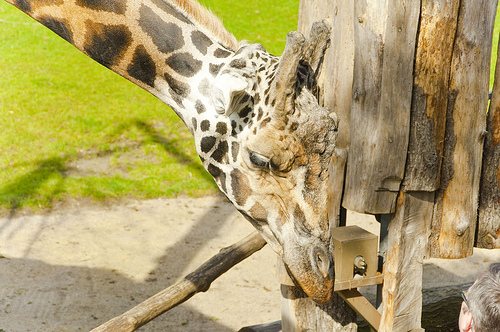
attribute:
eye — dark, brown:
[253, 158, 290, 184]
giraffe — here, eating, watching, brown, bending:
[185, 22, 337, 304]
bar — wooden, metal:
[357, 3, 478, 103]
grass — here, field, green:
[13, 73, 86, 111]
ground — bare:
[265, 13, 287, 20]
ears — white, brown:
[261, 24, 351, 116]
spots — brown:
[195, 137, 223, 165]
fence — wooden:
[396, 172, 490, 231]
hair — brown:
[477, 274, 498, 318]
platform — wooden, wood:
[455, 8, 492, 79]